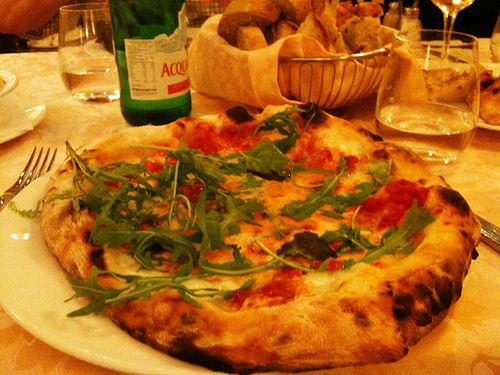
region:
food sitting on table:
[0, 0, 497, 373]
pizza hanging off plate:
[6, 90, 484, 370]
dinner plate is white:
[3, 140, 213, 367]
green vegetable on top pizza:
[56, 117, 444, 322]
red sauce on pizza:
[169, 110, 294, 164]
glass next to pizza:
[365, 18, 497, 190]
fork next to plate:
[0, 134, 102, 271]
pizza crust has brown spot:
[356, 256, 468, 342]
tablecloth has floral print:
[5, 44, 126, 151]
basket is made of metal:
[195, 0, 422, 130]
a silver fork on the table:
[1, 148, 56, 203]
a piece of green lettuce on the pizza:
[70, 278, 197, 315]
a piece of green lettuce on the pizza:
[91, 215, 193, 265]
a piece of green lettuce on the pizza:
[257, 215, 424, 275]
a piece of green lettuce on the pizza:
[281, 152, 344, 216]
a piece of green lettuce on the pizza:
[339, 154, 399, 216]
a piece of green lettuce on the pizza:
[237, 148, 294, 183]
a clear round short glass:
[380, 25, 477, 160]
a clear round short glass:
[56, 3, 126, 99]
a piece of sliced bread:
[218, 3, 274, 38]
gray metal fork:
[0, 144, 58, 214]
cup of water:
[372, 28, 481, 170]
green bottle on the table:
[109, 0, 195, 122]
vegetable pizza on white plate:
[46, 104, 478, 369]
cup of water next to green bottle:
[57, 1, 122, 103]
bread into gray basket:
[214, 2, 389, 61]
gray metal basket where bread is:
[199, 16, 403, 108]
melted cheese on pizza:
[103, 122, 428, 309]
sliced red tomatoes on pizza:
[149, 117, 426, 294]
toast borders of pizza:
[324, 182, 471, 366]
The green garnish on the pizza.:
[63, 129, 430, 304]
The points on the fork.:
[20, 145, 62, 180]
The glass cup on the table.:
[370, 26, 479, 141]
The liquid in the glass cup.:
[375, 119, 469, 159]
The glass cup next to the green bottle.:
[59, 5, 119, 99]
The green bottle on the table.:
[112, 3, 192, 120]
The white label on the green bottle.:
[127, 30, 187, 110]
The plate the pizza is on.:
[9, 139, 449, 374]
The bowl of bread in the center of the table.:
[200, 11, 401, 103]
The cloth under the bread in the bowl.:
[187, 13, 344, 112]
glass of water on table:
[390, 25, 475, 150]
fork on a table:
[11, 135, 51, 175]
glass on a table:
[52, 1, 114, 112]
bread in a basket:
[221, 11, 356, 86]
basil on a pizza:
[365, 197, 421, 263]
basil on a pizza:
[222, 242, 285, 288]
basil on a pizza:
[91, 267, 163, 303]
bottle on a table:
[98, 23, 203, 106]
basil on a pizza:
[182, 137, 223, 188]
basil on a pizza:
[91, 153, 146, 200]